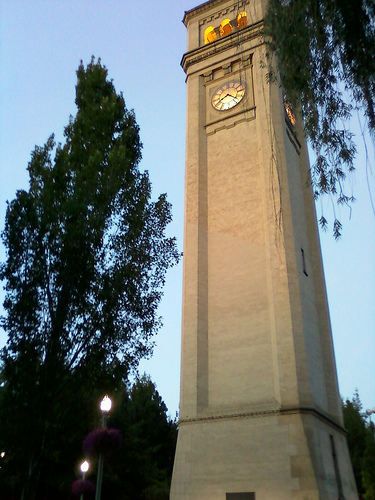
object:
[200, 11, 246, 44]
window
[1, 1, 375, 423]
sky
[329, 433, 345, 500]
door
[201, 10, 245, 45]
light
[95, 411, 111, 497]
lamp posts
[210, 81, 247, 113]
clock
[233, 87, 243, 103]
roman numerals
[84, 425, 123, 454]
flowers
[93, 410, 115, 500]
light poles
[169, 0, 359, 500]
clock tower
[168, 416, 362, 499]
stone base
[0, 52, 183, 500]
tree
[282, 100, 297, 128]
clock face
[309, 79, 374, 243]
branches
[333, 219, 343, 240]
leaves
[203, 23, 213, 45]
light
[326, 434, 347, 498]
entry door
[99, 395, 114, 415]
light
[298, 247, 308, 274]
window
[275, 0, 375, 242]
tree